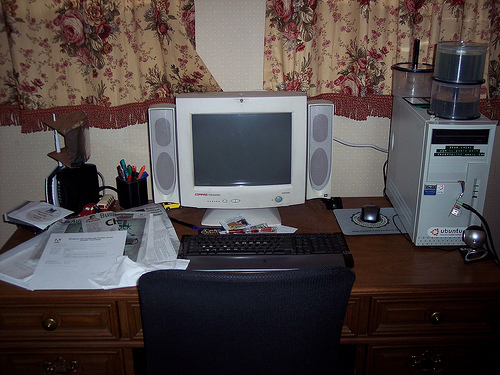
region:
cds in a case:
[423, 28, 493, 135]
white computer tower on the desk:
[366, 85, 489, 255]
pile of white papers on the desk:
[11, 202, 140, 327]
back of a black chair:
[117, 247, 372, 367]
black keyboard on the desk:
[168, 220, 356, 270]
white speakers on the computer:
[142, 96, 184, 215]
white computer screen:
[160, 87, 335, 237]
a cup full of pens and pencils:
[105, 152, 180, 234]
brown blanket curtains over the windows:
[0, 0, 213, 168]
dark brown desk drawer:
[0, 290, 136, 359]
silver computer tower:
[381, 96, 491, 265]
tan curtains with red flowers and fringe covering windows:
[2, 3, 495, 136]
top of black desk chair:
[130, 256, 364, 371]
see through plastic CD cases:
[385, 33, 494, 124]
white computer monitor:
[174, 94, 306, 231]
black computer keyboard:
[171, 228, 359, 268]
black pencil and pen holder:
[105, 153, 155, 210]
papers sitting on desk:
[3, 201, 190, 296]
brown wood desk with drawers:
[5, 218, 497, 371]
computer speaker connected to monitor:
[140, 98, 204, 213]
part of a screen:
[240, 131, 283, 186]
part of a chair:
[232, 257, 280, 312]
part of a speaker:
[311, 129, 333, 191]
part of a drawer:
[373, 274, 425, 351]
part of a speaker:
[455, 208, 485, 270]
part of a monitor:
[245, 110, 282, 154]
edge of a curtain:
[106, 118, 124, 134]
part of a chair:
[212, 241, 253, 303]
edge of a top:
[368, 265, 408, 308]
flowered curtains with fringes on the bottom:
[3, 2, 397, 117]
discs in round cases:
[427, 30, 489, 122]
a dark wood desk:
[0, 194, 497, 373]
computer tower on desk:
[386, 93, 492, 285]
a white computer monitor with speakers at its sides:
[143, 89, 335, 214]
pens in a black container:
[112, 153, 150, 209]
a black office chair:
[136, 265, 356, 363]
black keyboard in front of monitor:
[166, 96, 350, 259]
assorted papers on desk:
[0, 195, 190, 295]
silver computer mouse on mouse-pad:
[336, 202, 406, 237]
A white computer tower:
[379, 100, 494, 256]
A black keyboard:
[173, 227, 352, 267]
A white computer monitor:
[168, 87, 306, 232]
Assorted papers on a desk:
[10, 206, 185, 294]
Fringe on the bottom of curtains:
[7, 59, 143, 139]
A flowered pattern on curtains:
[6, 2, 393, 84]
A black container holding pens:
[107, 153, 152, 210]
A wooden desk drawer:
[3, 290, 137, 354]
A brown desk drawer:
[1, 291, 131, 351]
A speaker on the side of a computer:
[277, 96, 334, 207]